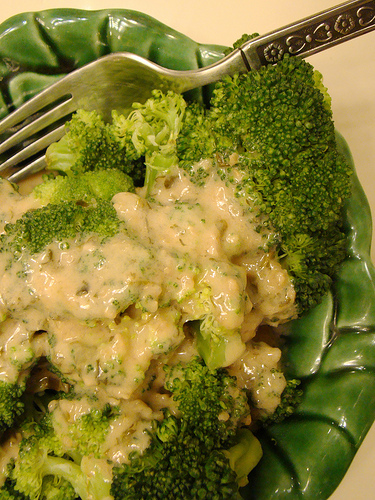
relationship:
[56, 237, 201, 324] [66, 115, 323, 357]
cheese on top of broccoli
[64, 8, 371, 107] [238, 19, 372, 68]
fork has handle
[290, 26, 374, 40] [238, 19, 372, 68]
design on handle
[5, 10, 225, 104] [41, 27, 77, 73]
bowl has cracks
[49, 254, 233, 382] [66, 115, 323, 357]
cheese sauce on broccoli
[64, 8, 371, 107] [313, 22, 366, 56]
fork has end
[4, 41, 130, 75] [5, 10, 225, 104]
groove carved in bowl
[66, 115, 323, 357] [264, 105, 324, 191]
broccoli has sproutlets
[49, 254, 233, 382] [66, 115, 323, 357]
cheese sauce over broccoli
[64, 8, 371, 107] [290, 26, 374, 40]
fork has design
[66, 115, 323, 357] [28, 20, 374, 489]
broccoli on top of plate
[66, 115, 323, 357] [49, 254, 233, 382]
broccoli has cheese sauce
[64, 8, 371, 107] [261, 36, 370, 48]
fork has tines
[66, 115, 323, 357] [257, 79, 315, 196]
broccoli has floret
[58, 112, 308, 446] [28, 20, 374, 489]
vegetable in plate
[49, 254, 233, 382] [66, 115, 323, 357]
cheese sauce covers broccoli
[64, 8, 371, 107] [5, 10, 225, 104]
fork resting on bowl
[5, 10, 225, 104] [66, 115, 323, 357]
bowl contains broccoli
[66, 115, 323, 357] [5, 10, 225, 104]
broccoli on top of bowl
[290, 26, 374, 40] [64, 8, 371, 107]
design on fork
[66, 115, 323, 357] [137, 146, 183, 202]
broccoli has stem